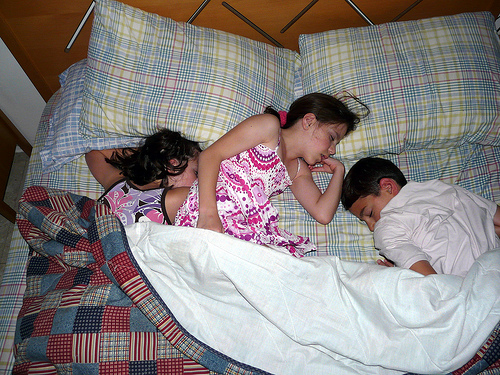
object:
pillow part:
[102, 35, 252, 131]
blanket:
[15, 185, 500, 375]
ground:
[394, 157, 417, 200]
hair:
[104, 127, 204, 189]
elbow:
[305, 204, 334, 225]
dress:
[174, 127, 318, 259]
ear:
[379, 178, 399, 197]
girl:
[85, 126, 203, 228]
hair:
[340, 156, 407, 210]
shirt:
[372, 179, 497, 278]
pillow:
[298, 11, 500, 162]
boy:
[340, 154, 500, 278]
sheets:
[0, 69, 500, 375]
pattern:
[244, 219, 276, 242]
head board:
[0, 0, 499, 102]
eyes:
[369, 210, 374, 217]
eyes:
[330, 134, 335, 141]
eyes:
[195, 170, 198, 176]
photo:
[3, 5, 496, 372]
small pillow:
[39, 58, 147, 176]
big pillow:
[78, 0, 301, 152]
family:
[84, 90, 499, 296]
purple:
[133, 202, 158, 214]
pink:
[256, 163, 270, 170]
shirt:
[97, 178, 173, 225]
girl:
[174, 92, 362, 257]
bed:
[1, 1, 498, 371]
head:
[341, 157, 409, 232]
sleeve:
[373, 216, 432, 269]